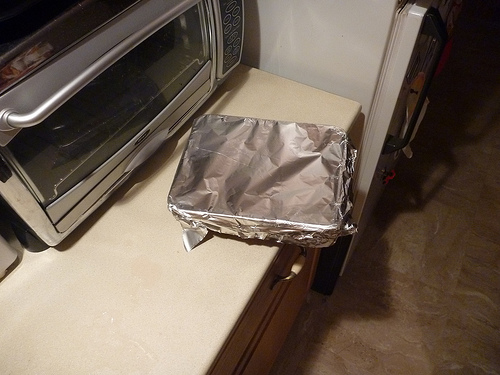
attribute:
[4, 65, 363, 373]
counter — white, ivory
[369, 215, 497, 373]
tiles — brown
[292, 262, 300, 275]
handle — ivory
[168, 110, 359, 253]
foil — silver, aluminum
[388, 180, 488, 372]
floor — biege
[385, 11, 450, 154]
handle — black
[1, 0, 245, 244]
oven — toaster, silver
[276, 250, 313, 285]
knob — gold, white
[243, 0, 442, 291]
refrigerator — white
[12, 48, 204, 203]
rack — metal, silver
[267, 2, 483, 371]
floor — brown, tan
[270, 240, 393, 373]
shadow — dark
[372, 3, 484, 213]
shadow — dark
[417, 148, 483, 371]
shadow — dark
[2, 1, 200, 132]
handle — silver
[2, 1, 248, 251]
toaster oven — digitally controlled, closed, stainless steel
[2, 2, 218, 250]
door — glass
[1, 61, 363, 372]
counter top — light colored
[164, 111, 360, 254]
aluminum foil — silver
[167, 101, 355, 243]
dish — baking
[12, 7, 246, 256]
oven — electronic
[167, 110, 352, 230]
foil — aluminum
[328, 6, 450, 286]
refrigerator door — closed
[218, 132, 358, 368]
drawer — closed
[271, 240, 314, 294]
drawer pull — ceramic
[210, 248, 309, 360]
drawer — wooden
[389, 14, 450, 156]
handles — refrigerator, door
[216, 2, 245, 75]
control panel — toaster oven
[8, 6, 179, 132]
door handle — toaster oven